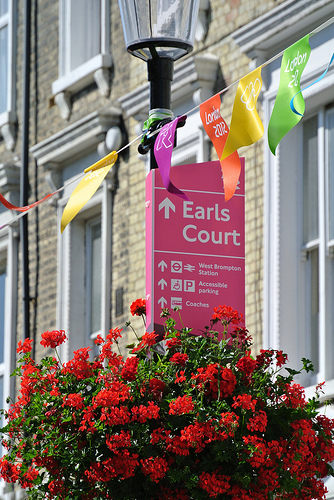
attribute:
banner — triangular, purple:
[150, 115, 180, 192]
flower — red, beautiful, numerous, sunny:
[129, 296, 153, 320]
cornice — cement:
[28, 112, 122, 175]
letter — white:
[182, 200, 194, 223]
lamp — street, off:
[113, 0, 204, 66]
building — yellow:
[1, 1, 333, 410]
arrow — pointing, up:
[157, 196, 178, 220]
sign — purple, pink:
[144, 152, 248, 352]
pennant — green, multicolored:
[263, 35, 314, 159]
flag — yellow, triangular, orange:
[57, 151, 121, 235]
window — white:
[301, 107, 333, 383]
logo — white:
[170, 278, 184, 296]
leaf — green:
[166, 315, 176, 329]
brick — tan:
[243, 183, 268, 204]